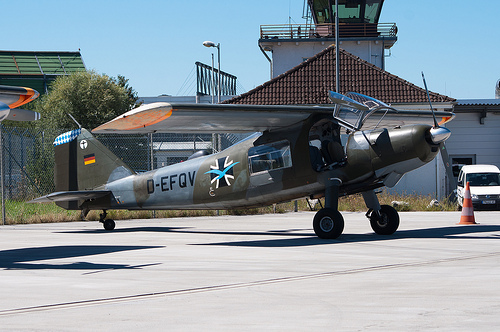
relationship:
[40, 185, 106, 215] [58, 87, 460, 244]
wing of plane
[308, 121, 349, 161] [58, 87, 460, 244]
cockpit on plane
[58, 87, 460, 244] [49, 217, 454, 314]
plane on ground